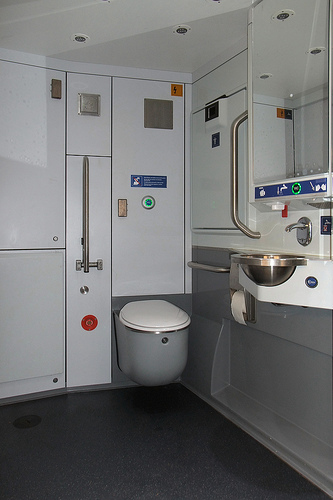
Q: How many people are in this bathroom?
A: None.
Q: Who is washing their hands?
A: No one.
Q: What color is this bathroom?
A: White.